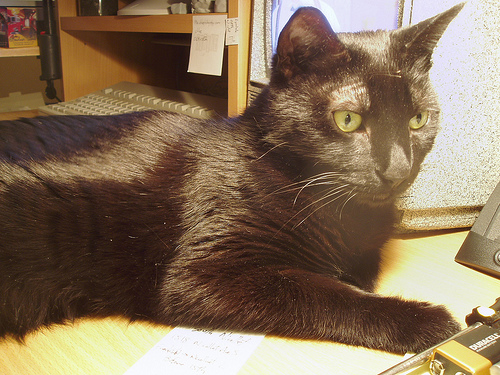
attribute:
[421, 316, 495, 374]
battery — duracell, sitting, white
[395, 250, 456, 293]
table — wooden, brown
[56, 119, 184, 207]
fur — shiny, cat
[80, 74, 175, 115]
keyboard — computer, white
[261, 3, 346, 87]
ear — black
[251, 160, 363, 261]
whisker — long, part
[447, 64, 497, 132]
light — reflecting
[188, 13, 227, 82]
paper — white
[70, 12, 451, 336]
cat — large, black, yellow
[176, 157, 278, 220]
spot — tiny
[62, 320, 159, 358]
desk — wood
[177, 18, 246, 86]
post-it — white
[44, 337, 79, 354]
surface — wood